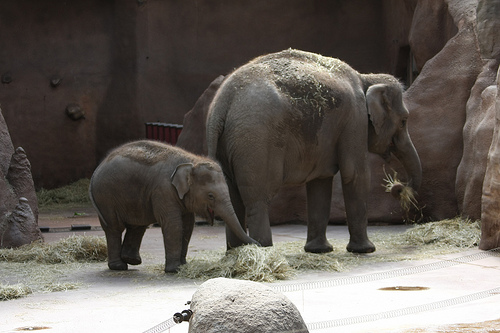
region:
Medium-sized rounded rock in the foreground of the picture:
[180, 265, 317, 331]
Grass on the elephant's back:
[232, 41, 362, 123]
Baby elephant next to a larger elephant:
[73, 130, 283, 275]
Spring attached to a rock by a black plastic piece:
[129, 303, 203, 331]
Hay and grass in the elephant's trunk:
[382, 168, 420, 212]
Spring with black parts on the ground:
[32, 213, 106, 235]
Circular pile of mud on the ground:
[370, 276, 433, 300]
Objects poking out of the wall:
[44, 72, 91, 129]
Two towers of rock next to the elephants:
[5, 145, 42, 251]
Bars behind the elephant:
[140, 111, 188, 145]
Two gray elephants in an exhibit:
[84, 46, 424, 271]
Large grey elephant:
[201, 45, 429, 257]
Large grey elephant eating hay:
[202, 47, 429, 256]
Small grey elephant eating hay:
[85, 136, 262, 276]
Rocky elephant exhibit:
[0, 0, 497, 331]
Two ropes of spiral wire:
[264, 243, 498, 332]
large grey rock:
[187, 273, 309, 332]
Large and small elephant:
[85, 43, 422, 280]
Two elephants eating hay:
[82, 45, 426, 272]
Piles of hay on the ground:
[2, 210, 482, 305]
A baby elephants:
[88, 140, 255, 272]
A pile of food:
[185, 240, 346, 280]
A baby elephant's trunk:
[225, 207, 259, 250]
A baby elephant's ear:
[169, 162, 196, 197]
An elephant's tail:
[82, 181, 105, 225]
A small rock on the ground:
[190, 275, 300, 328]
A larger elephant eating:
[205, 55, 425, 250]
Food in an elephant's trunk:
[380, 170, 415, 205]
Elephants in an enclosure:
[5, 0, 495, 330]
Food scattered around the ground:
[0, 181, 498, 328]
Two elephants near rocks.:
[70, 35, 440, 280]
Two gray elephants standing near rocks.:
[80, 30, 443, 290]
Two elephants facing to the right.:
[70, 35, 445, 285]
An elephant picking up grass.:
[190, 30, 446, 290]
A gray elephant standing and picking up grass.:
[190, 30, 451, 285]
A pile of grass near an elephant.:
[195, 35, 490, 285]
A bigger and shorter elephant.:
[75, 35, 431, 280]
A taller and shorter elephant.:
[75, 35, 435, 285]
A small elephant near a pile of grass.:
[75, 125, 305, 290]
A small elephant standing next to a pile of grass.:
[66, 126, 301, 294]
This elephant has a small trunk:
[229, 222, 271, 264]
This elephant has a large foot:
[357, 233, 374, 265]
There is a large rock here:
[231, 292, 239, 324]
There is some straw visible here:
[245, 248, 255, 273]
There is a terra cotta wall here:
[46, 99, 73, 171]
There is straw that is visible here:
[248, 250, 267, 280]